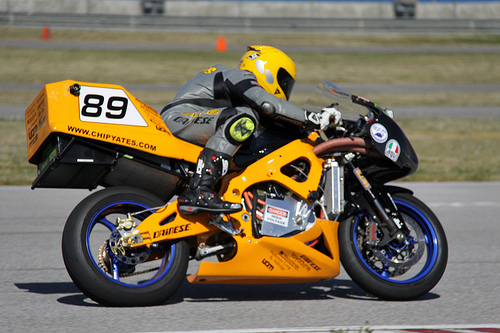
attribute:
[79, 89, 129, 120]
writing — black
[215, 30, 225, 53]
cone — pink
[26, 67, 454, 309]
motorbike — yellow, orange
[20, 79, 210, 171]
seat — orange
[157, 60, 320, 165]
outfit — gray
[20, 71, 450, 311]
bike — motorized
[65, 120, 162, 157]
info — site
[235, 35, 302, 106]
helmet — yellow, light orange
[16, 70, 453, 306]
racing motorcycle — dark yellow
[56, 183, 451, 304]
motorcycle tires — high performance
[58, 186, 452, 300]
motorcycle wheel/rims — dark blue, stylish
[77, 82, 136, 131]
racing number — motorcycle's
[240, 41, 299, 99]
yellow helmet — sturdy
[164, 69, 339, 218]
motorcycle racesuit — skin-tight, gray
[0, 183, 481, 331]
racing track — concrete, gray